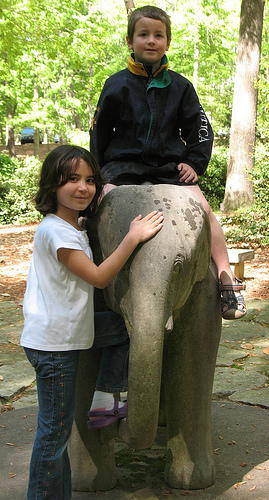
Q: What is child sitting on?
A: Elephant.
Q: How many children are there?
A: Two.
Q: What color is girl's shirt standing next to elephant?
A: White.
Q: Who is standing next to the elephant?
A: Girl.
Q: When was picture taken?
A: Daytime.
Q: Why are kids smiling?
A: Picture.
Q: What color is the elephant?
A: Grey.